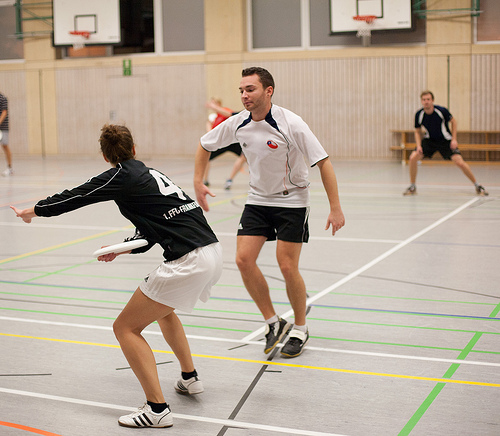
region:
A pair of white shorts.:
[131, 205, 275, 302]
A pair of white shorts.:
[125, 237, 229, 335]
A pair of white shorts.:
[80, 220, 278, 422]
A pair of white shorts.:
[48, 117, 212, 278]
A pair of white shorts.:
[115, 168, 207, 305]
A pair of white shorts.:
[110, 188, 237, 373]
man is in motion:
[190, 62, 347, 364]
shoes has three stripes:
[106, 408, 176, 430]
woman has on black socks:
[11, 106, 227, 433]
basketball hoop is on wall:
[327, 1, 415, 46]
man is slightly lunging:
[398, 90, 495, 203]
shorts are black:
[236, 202, 313, 243]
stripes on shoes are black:
[116, 400, 173, 430]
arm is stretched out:
[4, 163, 125, 223]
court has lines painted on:
[1, 155, 497, 433]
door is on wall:
[101, 73, 162, 161]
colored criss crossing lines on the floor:
[347, 279, 457, 401]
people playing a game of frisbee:
[13, 60, 370, 428]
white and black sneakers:
[101, 370, 238, 432]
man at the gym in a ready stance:
[385, 82, 487, 218]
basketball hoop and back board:
[324, 2, 424, 41]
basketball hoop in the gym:
[46, 3, 135, 53]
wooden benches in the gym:
[387, 110, 492, 166]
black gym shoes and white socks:
[258, 314, 315, 366]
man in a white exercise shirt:
[193, 61, 345, 211]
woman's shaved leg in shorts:
[111, 285, 167, 394]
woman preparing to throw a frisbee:
[85, 129, 209, 268]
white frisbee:
[83, 235, 154, 259]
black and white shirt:
[187, 113, 333, 207]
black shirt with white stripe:
[409, 109, 459, 154]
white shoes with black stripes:
[117, 402, 173, 432]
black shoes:
[266, 314, 308, 358]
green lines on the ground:
[354, 313, 494, 388]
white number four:
[143, 169, 200, 219]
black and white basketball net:
[323, 6, 422, 49]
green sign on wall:
[117, 52, 147, 89]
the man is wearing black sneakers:
[263, 315, 328, 363]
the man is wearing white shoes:
[110, 405, 205, 432]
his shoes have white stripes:
[110, 395, 195, 434]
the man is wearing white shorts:
[91, 211, 259, 310]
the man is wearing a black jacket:
[56, 144, 221, 296]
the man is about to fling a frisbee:
[78, 237, 182, 271]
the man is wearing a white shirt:
[222, 120, 325, 214]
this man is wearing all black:
[402, 78, 476, 218]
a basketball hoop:
[53, 22, 104, 66]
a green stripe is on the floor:
[426, 303, 493, 433]